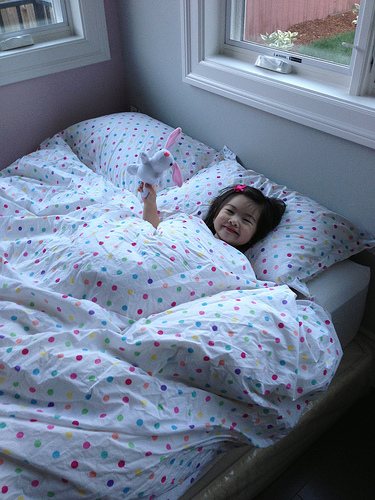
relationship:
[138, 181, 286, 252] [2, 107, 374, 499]
girl lying on bed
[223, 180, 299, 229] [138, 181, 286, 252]
hair of girl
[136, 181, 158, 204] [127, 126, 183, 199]
right hand holding bunny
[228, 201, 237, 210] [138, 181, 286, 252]
eyebrow of girl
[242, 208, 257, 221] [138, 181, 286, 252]
eyebrow of girl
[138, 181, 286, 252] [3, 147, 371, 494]
girl laying in bed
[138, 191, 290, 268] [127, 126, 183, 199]
girl has bunny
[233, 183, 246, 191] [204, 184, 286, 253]
pink bow in hair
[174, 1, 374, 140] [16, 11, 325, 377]
window in room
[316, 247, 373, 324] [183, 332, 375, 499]
sheet on mattress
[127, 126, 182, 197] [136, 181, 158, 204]
bunny in right hand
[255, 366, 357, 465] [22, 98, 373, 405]
mattress on bed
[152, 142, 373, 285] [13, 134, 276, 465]
pollow on bed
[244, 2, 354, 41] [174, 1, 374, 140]
fence out window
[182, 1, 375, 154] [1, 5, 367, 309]
window in room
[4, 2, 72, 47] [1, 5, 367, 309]
window in room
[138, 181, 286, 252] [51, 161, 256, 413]
girl looks comfortable in bed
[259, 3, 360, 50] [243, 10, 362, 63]
plants seen outside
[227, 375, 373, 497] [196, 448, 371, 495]
foundation on floor